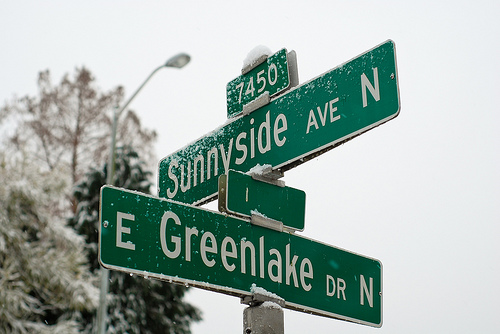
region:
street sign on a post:
[89, 178, 394, 315]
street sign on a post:
[161, 62, 405, 199]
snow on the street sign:
[165, 143, 208, 158]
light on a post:
[162, 50, 190, 76]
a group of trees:
[5, 80, 101, 318]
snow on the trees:
[53, 217, 88, 285]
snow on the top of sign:
[241, 37, 276, 74]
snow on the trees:
[117, 290, 185, 326]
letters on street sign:
[163, 209, 238, 276]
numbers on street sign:
[227, 65, 281, 104]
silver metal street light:
[159, 31, 204, 87]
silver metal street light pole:
[90, 270, 115, 330]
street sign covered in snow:
[212, 36, 295, 112]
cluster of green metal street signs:
[82, 27, 442, 328]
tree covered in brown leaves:
[13, 52, 105, 164]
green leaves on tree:
[127, 287, 195, 332]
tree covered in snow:
[7, 178, 97, 330]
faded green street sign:
[209, 168, 319, 228]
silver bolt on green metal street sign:
[96, 212, 114, 233]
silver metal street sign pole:
[233, 288, 292, 332]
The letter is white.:
[110, 201, 145, 256]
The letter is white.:
[348, 60, 388, 119]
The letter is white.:
[351, 260, 378, 319]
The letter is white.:
[151, 200, 187, 272]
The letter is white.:
[180, 215, 202, 272]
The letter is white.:
[195, 225, 222, 274]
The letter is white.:
[217, 227, 241, 279]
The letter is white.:
[236, 230, 261, 285]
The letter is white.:
[253, 222, 269, 288]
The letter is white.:
[263, 236, 285, 289]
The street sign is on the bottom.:
[93, 182, 409, 328]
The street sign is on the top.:
[154, 56, 446, 202]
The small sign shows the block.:
[225, 51, 297, 101]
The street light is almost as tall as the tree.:
[106, 50, 206, 117]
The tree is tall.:
[3, 62, 182, 327]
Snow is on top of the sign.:
[241, 40, 275, 68]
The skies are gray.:
[393, 134, 488, 236]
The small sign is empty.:
[222, 165, 317, 231]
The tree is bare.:
[11, 57, 136, 167]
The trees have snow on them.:
[17, 188, 90, 318]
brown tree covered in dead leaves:
[0, 62, 107, 161]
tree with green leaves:
[7, 182, 94, 332]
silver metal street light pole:
[102, 70, 127, 181]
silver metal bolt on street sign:
[93, 210, 112, 235]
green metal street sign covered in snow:
[215, 37, 300, 108]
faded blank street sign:
[215, 162, 336, 226]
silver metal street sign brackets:
[249, 159, 293, 188]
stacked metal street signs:
[105, 42, 418, 327]